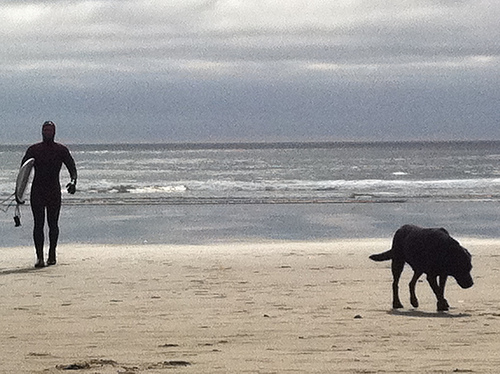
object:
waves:
[3, 143, 499, 203]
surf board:
[12, 156, 35, 202]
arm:
[61, 144, 79, 180]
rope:
[0, 191, 22, 228]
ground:
[379, 172, 402, 194]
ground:
[0, 240, 499, 373]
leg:
[408, 270, 419, 300]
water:
[0, 140, 498, 244]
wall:
[348, 96, 395, 155]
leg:
[436, 270, 448, 303]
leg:
[423, 271, 442, 300]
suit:
[19, 120, 77, 269]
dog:
[369, 215, 476, 314]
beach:
[0, 0, 499, 374]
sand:
[0, 198, 499, 374]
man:
[18, 121, 78, 266]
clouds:
[0, 0, 499, 110]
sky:
[0, 0, 499, 147]